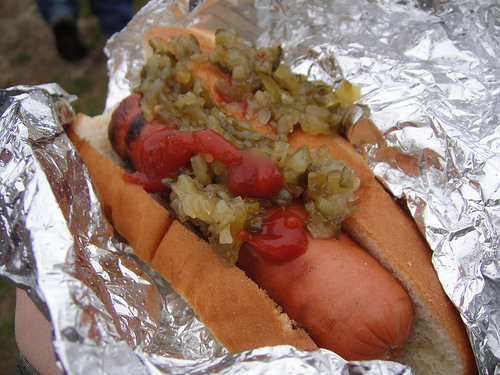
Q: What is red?
A: Ketchup.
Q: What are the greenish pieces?
A: Relish.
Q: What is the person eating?
A: A hotdog.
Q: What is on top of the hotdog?
A: Ketchup and relish.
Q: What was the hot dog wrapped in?
A: Foil;.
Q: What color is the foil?
A: Silver.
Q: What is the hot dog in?
A: A bun.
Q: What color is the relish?
A: Green.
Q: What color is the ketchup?
A: Red.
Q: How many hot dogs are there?
A: One.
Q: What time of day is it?
A: Daylight hours.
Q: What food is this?
A: Hot dog in a bun.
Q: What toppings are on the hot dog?
A: Ketchup and relish.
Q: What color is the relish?
A: Green.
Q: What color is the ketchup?
A: Red.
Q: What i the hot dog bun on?
A: Foil.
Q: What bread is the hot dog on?
A: White bread.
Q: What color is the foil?
A: Silver.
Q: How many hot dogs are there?
A: One.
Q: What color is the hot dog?
A: Tan.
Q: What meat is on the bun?
A: A hotdog.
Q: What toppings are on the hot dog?
A: Ketchup and mustard.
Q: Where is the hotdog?
A: In aluminum foil.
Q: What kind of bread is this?
A: White.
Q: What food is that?
A: Hot dog.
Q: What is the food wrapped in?
A: Tin foil.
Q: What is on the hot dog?
A: Relish.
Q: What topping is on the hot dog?
A: Ketchup.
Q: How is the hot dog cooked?
A: Grilled.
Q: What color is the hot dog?
A: Pinkish brown.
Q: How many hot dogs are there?
A: One.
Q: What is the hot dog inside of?
A: A bun.